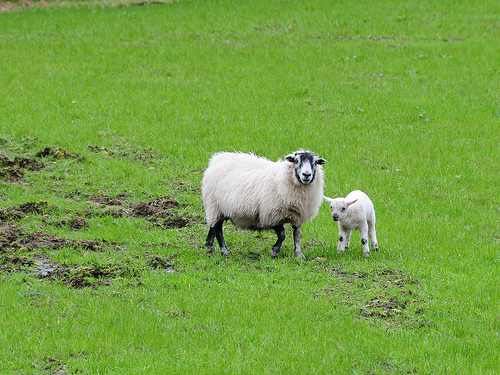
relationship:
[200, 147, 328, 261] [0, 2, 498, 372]
lamb in field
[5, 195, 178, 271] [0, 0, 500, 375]
area in area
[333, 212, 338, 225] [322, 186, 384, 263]
nose on baby lamb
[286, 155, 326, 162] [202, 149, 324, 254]
ears are on sheep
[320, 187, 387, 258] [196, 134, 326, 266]
baby lamb with mother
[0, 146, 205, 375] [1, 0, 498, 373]
hole in ground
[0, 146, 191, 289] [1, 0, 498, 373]
hole in ground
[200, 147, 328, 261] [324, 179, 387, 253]
lamb with its baby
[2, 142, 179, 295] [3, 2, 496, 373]
dirt in grass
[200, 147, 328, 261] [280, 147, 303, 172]
lamb has ear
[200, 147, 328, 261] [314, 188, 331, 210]
lamb has ear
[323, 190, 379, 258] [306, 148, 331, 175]
baby lamb has ear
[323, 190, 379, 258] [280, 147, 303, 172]
baby lamb has ear